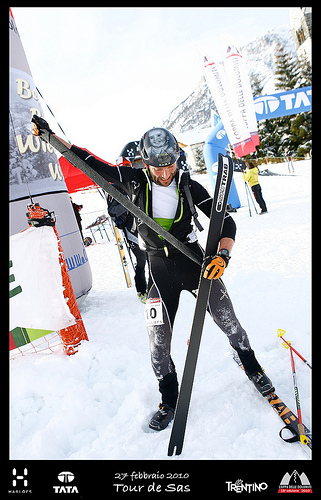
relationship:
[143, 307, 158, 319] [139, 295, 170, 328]
number on sticker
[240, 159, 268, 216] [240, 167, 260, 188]
person with shirt